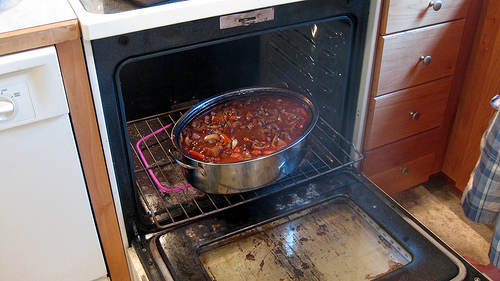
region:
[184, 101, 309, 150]
The stew is red.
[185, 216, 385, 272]
The oven is dirty.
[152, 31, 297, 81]
The oven is black.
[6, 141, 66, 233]
The dishwasher is white.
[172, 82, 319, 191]
The pot is silver.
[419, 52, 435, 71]
The cabinet has a knob.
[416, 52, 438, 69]
The knob is silver.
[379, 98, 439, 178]
The cabinets are wood.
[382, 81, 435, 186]
The cabinets are brown.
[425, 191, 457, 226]
The floor is biege.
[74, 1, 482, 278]
the electric oven door is open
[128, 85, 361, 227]
a grate is partially pulled out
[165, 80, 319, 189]
a large pot of beef stew is cooking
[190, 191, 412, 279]
the window on the oven door is greasy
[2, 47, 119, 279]
the dishwasher is next to the oven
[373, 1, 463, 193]
drawers are next to the oven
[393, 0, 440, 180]
the drawers have gold knobs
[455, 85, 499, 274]
the person has a plaid shitr on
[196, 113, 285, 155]
carrots, mushrooms, and potatoes are in the stew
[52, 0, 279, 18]
the stove has a smooth top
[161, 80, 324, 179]
pot of stew in oven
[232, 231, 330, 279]
built up food on oven door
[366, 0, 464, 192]
drawers in the kitchen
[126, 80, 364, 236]
wire rack holding pot with stew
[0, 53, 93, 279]
dishwasher that is white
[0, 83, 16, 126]
knob to control dishwasher settings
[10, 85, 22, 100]
lettering indicating dish wash cycle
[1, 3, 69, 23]
counter top above dish washer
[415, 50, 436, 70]
knob to open drawer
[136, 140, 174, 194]
heated wire in oven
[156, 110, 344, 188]
black pot in oven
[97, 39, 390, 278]
black inside of oven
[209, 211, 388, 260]
dirty inside of oven door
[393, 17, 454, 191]
wood colored drawers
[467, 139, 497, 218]
blue and white rag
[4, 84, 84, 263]
white colored small dishwasher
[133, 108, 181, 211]
pink lit hot coil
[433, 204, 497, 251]
tan colored kitchen floor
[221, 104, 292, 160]
beef stew inside pot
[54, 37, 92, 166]
wood frame around dishwasher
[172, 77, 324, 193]
a dish in the oven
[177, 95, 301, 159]
soup in the dish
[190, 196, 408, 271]
the oven door is open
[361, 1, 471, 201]
drawers next to the oven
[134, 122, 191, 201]
the oven element is pink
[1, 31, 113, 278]
a dishwasher next to the oven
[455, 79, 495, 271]
the edge of a skirt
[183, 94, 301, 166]
carrots in the soup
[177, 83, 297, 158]
mushroom in the soup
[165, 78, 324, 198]
the dish is silver